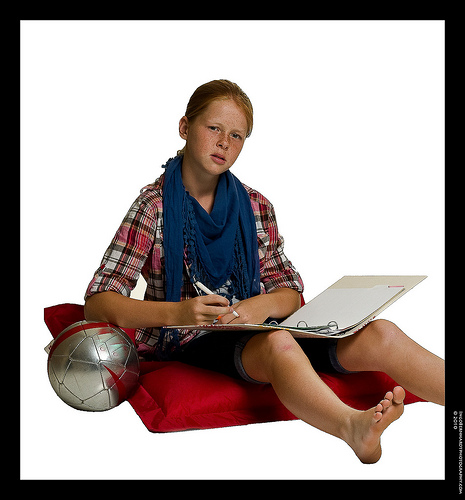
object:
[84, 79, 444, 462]
girl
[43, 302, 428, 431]
pillow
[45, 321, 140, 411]
ball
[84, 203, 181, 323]
arm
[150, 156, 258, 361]
scarf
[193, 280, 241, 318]
pen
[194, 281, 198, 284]
top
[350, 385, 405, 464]
foot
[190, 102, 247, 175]
face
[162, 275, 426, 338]
note book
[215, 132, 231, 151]
nose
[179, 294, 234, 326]
hand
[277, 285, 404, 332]
paper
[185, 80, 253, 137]
red hair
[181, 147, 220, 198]
neck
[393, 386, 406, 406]
toes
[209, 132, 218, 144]
freckles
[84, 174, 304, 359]
shirt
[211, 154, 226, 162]
lip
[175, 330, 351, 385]
shorts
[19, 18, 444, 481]
floor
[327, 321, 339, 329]
ring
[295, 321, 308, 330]
ring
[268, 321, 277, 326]
ring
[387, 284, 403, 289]
tabbed divider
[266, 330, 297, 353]
knee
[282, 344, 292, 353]
scar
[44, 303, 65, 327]
corner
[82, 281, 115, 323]
elbow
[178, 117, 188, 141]
right ear